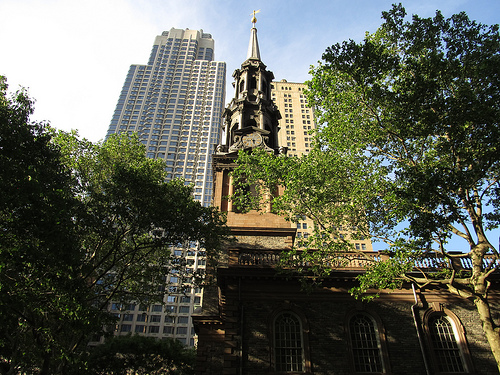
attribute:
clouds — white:
[22, 14, 149, 105]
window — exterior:
[426, 308, 468, 373]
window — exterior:
[348, 315, 386, 375]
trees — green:
[42, 169, 199, 310]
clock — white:
[233, 126, 266, 152]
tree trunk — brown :
[451, 269, 498, 316]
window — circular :
[267, 309, 309, 374]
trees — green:
[9, 23, 498, 369]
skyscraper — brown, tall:
[100, 12, 313, 374]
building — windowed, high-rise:
[68, 31, 299, 351]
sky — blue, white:
[279, 7, 329, 57]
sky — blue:
[310, 8, 349, 35]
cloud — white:
[1, 0, 174, 145]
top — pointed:
[247, 11, 261, 61]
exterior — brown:
[378, 290, 413, 305]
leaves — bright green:
[324, 73, 394, 143]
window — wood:
[274, 311, 303, 371]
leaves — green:
[324, 85, 381, 145]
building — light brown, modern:
[273, 78, 369, 254]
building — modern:
[101, 20, 223, 343]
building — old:
[222, 250, 462, 373]